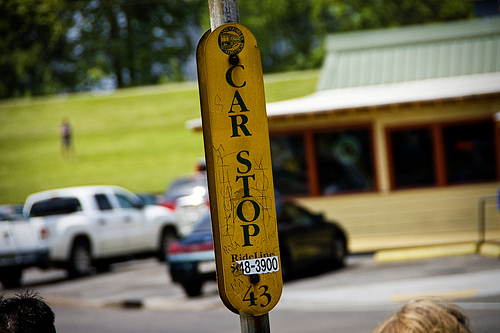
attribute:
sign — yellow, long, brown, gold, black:
[193, 21, 296, 321]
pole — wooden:
[224, 295, 302, 330]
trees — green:
[3, 2, 142, 99]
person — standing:
[59, 103, 86, 172]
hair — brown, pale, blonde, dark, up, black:
[9, 295, 54, 331]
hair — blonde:
[398, 296, 463, 330]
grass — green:
[10, 133, 204, 184]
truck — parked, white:
[16, 196, 176, 277]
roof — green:
[318, 22, 493, 67]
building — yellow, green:
[282, 37, 499, 240]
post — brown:
[193, 10, 300, 332]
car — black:
[170, 204, 353, 276]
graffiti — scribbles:
[216, 148, 236, 257]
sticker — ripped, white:
[235, 256, 293, 281]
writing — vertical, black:
[220, 62, 261, 273]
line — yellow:
[388, 290, 487, 304]